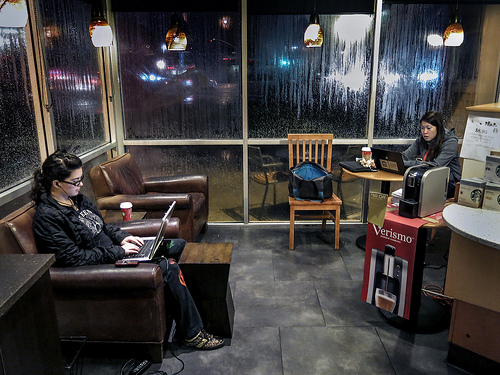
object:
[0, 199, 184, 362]
chair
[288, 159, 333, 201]
purse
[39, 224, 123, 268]
arm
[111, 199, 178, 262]
laptop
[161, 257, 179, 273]
lap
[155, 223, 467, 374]
floor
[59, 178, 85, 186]
glasses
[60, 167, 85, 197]
face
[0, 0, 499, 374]
room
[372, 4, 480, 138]
glass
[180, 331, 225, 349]
shoes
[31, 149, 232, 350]
girl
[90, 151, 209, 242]
chair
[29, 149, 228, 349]
woman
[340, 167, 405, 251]
table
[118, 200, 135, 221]
cup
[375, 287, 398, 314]
coffee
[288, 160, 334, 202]
bag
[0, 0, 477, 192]
rain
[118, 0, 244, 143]
window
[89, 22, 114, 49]
lights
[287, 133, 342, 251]
chair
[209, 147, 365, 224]
patio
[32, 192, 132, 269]
black jacket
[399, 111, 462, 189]
woman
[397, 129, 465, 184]
grey jacket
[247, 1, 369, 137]
glass windows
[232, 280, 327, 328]
grey tile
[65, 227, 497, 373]
study floor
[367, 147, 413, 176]
laptop computer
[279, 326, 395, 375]
tile formation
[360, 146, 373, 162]
coffee cup